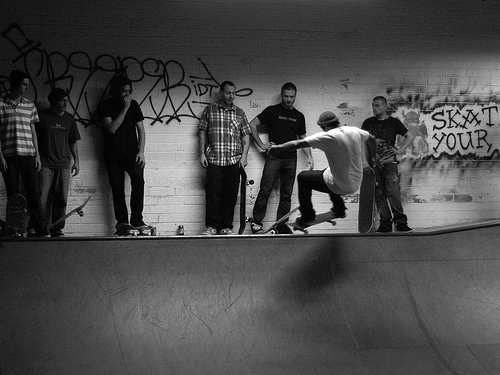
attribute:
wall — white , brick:
[2, 2, 498, 238]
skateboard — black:
[282, 203, 352, 242]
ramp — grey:
[0, 217, 498, 370]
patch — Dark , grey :
[457, 326, 497, 370]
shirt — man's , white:
[302, 115, 374, 203]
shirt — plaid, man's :
[199, 100, 254, 167]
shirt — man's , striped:
[5, 94, 41, 155]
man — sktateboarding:
[267, 100, 377, 230]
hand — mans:
[391, 138, 406, 169]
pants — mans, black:
[293, 163, 353, 227]